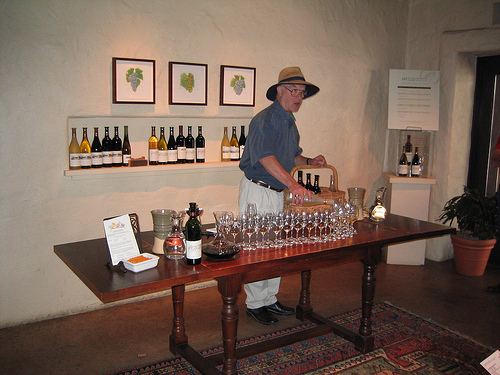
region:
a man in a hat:
[207, 49, 348, 327]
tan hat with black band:
[247, 62, 319, 108]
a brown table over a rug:
[43, 205, 471, 373]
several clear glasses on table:
[213, 190, 366, 247]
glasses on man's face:
[275, 81, 305, 99]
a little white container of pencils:
[120, 241, 166, 275]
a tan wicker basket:
[280, 165, 360, 221]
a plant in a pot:
[435, 165, 493, 295]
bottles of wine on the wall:
[64, 120, 265, 172]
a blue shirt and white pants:
[230, 95, 312, 317]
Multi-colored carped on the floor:
[91, 293, 499, 374]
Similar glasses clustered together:
[208, 196, 356, 259]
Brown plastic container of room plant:
[433, 182, 499, 282]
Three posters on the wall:
[103, 67, 261, 109]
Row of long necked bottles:
[64, 118, 247, 171]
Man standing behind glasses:
[233, 67, 334, 332]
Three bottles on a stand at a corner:
[374, 66, 449, 270]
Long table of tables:
[49, 179, 459, 374]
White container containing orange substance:
[121, 250, 163, 273]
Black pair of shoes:
[243, 297, 300, 328]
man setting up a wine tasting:
[57, 54, 454, 371]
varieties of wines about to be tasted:
[69, 119, 248, 166]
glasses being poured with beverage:
[212, 200, 355, 248]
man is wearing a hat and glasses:
[266, 65, 318, 101]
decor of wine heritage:
[113, 53, 260, 104]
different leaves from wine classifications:
[112, 57, 254, 104]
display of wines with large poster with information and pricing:
[386, 65, 429, 262]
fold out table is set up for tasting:
[51, 203, 453, 374]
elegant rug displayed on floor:
[106, 303, 498, 373]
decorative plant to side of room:
[434, 183, 498, 273]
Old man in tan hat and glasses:
[263, 64, 320, 113]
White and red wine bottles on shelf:
[66, 122, 136, 174]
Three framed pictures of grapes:
[108, 57, 259, 104]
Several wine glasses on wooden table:
[209, 205, 356, 253]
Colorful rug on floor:
[140, 298, 499, 374]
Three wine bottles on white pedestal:
[386, 128, 433, 269]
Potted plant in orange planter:
[437, 173, 497, 278]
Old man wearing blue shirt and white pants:
[235, 66, 315, 315]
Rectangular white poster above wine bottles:
[386, 66, 448, 173]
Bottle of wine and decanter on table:
[182, 202, 239, 266]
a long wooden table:
[50, 191, 460, 372]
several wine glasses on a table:
[210, 199, 362, 249]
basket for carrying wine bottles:
[277, 152, 353, 224]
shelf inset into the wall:
[54, 110, 273, 175]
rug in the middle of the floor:
[71, 295, 498, 373]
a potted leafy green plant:
[436, 189, 498, 283]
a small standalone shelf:
[379, 55, 444, 272]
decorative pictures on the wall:
[102, 49, 263, 109]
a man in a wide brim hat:
[235, 60, 336, 330]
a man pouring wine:
[232, 56, 367, 324]